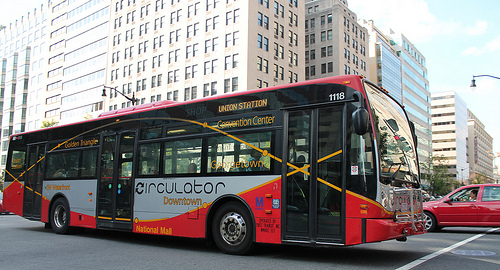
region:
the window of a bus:
[47, 147, 82, 181]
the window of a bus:
[77, 146, 97, 178]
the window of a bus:
[140, 139, 161, 174]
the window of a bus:
[162, 133, 202, 175]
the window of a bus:
[205, 129, 275, 174]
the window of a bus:
[362, 80, 419, 185]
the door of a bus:
[24, 139, 43, 219]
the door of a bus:
[96, 128, 135, 223]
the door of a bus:
[285, 100, 344, 242]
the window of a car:
[451, 185, 477, 205]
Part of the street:
[23, 243, 80, 265]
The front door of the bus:
[278, 94, 353, 251]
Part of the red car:
[448, 211, 478, 225]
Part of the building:
[244, 29, 251, 51]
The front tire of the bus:
[206, 194, 256, 256]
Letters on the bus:
[216, 97, 271, 115]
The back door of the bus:
[19, 137, 51, 224]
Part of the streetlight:
[471, 75, 476, 86]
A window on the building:
[223, 29, 232, 49]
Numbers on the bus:
[325, 87, 350, 102]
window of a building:
[107, 63, 124, 80]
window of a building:
[117, 60, 135, 80]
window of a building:
[130, 56, 148, 81]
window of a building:
[148, 45, 167, 75]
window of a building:
[166, 47, 182, 73]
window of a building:
[183, 41, 197, 59]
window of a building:
[253, 10, 273, 27]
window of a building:
[253, 26, 272, 49]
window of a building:
[252, 49, 272, 71]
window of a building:
[270, 53, 285, 80]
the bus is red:
[179, 221, 199, 234]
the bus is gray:
[143, 201, 161, 216]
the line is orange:
[319, 176, 334, 190]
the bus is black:
[278, 93, 304, 106]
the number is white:
[324, 90, 349, 104]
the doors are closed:
[294, 118, 326, 220]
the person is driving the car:
[461, 186, 483, 208]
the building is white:
[239, 25, 251, 55]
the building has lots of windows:
[151, 26, 195, 67]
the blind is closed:
[326, 26, 333, 41]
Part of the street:
[41, 246, 91, 263]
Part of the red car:
[454, 209, 476, 221]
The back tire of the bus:
[44, 192, 72, 237]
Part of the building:
[246, 37, 256, 54]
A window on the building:
[230, 51, 240, 71]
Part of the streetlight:
[470, 79, 476, 86]